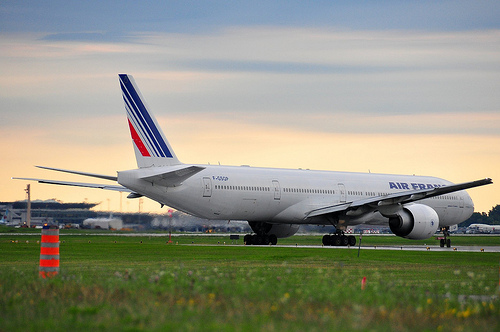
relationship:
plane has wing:
[12, 73, 494, 245] [310, 175, 492, 220]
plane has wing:
[12, 73, 494, 245] [9, 175, 129, 198]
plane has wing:
[12, 73, 494, 245] [360, 176, 495, 207]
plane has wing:
[12, 73, 494, 245] [41, 165, 125, 190]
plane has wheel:
[12, 73, 494, 245] [236, 221, 318, 248]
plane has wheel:
[12, 73, 494, 245] [322, 234, 360, 242]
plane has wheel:
[12, 73, 494, 245] [431, 231, 458, 246]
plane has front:
[12, 73, 494, 245] [419, 169, 480, 236]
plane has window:
[96, 95, 464, 254] [262, 184, 273, 200]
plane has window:
[12, 73, 494, 245] [216, 179, 235, 192]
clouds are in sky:
[220, 23, 499, 45] [6, 0, 499, 230]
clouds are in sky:
[1, 0, 499, 205] [6, 0, 499, 230]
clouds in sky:
[1, 0, 499, 205] [2, 1, 497, 33]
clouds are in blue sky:
[1, 0, 499, 205] [0, 1, 498, 213]